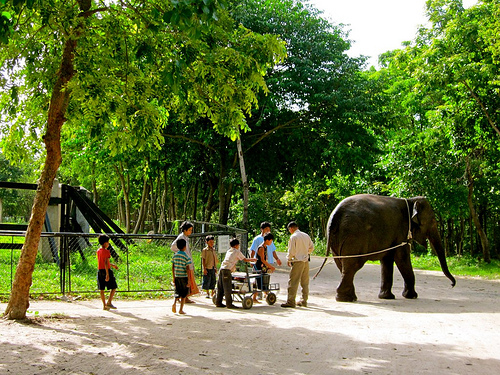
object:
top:
[256, 244, 268, 266]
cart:
[212, 263, 280, 309]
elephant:
[313, 194, 456, 302]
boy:
[96, 233, 274, 314]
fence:
[0, 220, 248, 295]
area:
[2, 221, 246, 294]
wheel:
[266, 292, 276, 304]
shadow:
[295, 308, 368, 317]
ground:
[364, 280, 423, 312]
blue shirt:
[250, 235, 276, 263]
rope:
[402, 198, 412, 239]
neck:
[403, 199, 412, 240]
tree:
[0, 0, 287, 320]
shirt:
[171, 250, 193, 277]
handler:
[281, 221, 314, 308]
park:
[0, 0, 500, 375]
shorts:
[97, 269, 117, 290]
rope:
[311, 242, 408, 258]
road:
[0, 248, 500, 374]